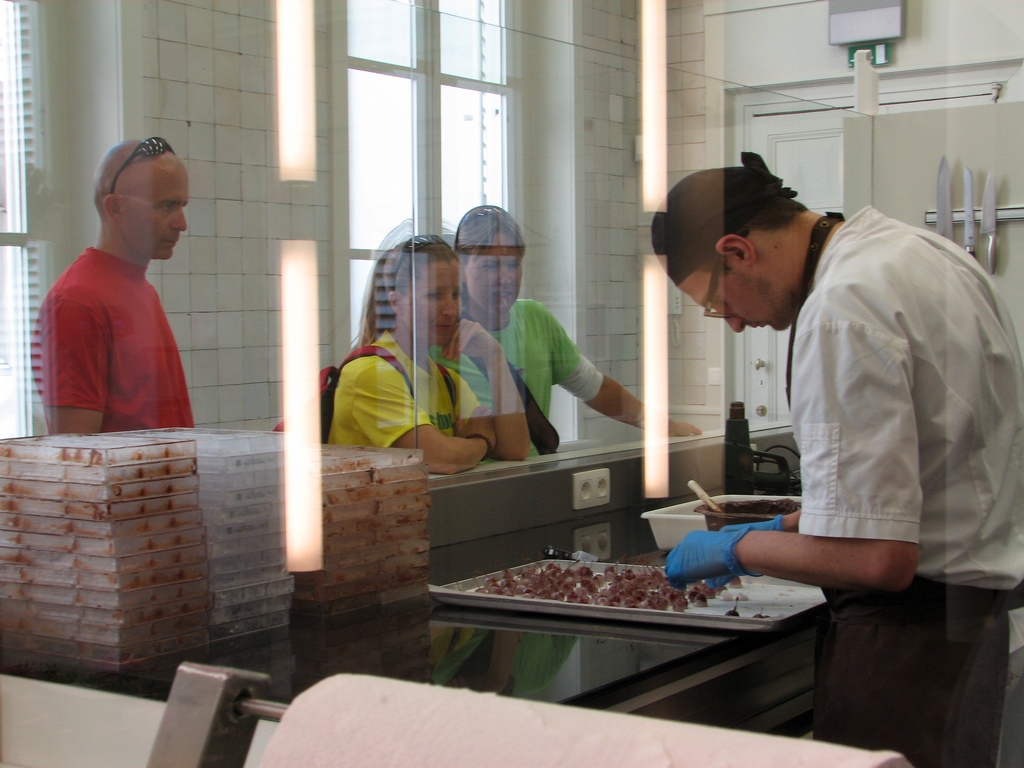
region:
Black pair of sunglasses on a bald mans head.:
[108, 133, 175, 198]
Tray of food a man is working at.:
[425, 555, 830, 636]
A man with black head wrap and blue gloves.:
[651, 152, 1022, 766]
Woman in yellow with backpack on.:
[323, 236, 532, 477]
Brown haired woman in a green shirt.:
[449, 204, 699, 460]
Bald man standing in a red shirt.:
[32, 135, 195, 429]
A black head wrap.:
[654, 153, 798, 287]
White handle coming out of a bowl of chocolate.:
[684, 478, 723, 516]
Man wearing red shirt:
[27, 241, 192, 432]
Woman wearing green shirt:
[440, 294, 600, 469]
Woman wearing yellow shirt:
[320, 334, 486, 464]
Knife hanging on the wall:
[958, 165, 974, 263]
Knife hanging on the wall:
[978, 164, 1001, 272]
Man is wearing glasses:
[103, 130, 173, 201]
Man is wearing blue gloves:
[664, 508, 788, 597]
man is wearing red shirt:
[0, 107, 222, 465]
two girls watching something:
[284, 179, 702, 470]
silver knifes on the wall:
[922, 139, 1003, 286]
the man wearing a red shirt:
[29, 135, 194, 431]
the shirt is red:
[30, 240, 193, 430]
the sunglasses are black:
[108, 138, 175, 199]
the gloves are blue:
[664, 512, 786, 589]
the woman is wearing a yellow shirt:
[324, 230, 525, 475]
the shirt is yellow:
[321, 328, 484, 461]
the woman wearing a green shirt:
[452, 200, 697, 450]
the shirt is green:
[437, 294, 575, 449]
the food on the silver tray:
[434, 553, 831, 639]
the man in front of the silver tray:
[428, 148, 1018, 765]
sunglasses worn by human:
[109, 131, 176, 192]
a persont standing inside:
[693, 165, 973, 720]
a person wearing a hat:
[579, 110, 947, 586]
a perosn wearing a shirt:
[734, 148, 932, 522]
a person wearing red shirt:
[2, 165, 317, 554]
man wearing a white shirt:
[774, 177, 1018, 612]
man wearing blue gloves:
[666, 505, 790, 589]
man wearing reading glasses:
[680, 262, 739, 336]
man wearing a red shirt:
[24, 239, 214, 436]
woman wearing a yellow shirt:
[318, 326, 500, 473]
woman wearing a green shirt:
[454, 294, 598, 431]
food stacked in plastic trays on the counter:
[18, 408, 215, 704]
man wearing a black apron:
[762, 224, 998, 756]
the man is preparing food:
[640, 151, 1015, 746]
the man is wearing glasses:
[699, 269, 729, 315]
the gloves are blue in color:
[673, 511, 782, 589]